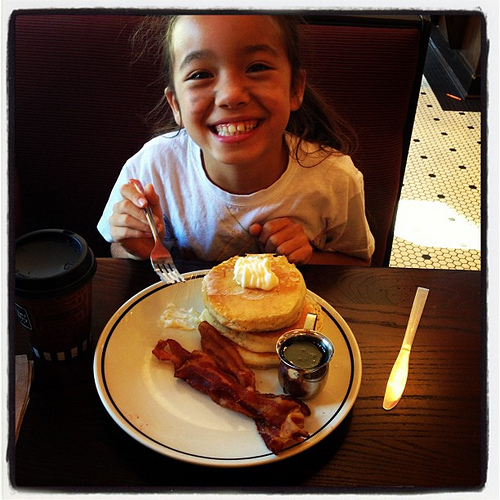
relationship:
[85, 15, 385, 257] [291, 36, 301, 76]
girl has brown hair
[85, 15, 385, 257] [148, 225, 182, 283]
girl holding fork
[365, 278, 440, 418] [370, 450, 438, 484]
knife on top of table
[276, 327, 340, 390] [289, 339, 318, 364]
cup of syrup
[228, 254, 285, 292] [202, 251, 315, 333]
butter on pancakes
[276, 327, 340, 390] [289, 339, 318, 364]
teacup has syrup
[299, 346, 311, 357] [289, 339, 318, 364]
bubbles in syrup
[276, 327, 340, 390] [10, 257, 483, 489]
cup on top of table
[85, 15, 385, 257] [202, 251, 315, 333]
girl eating pancakes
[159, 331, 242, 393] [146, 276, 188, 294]
bacon on plate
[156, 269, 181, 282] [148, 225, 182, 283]
cream on fork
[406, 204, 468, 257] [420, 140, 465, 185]
light reflection on floor